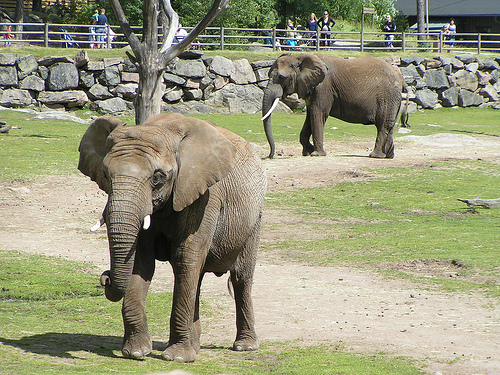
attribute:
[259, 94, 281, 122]
tusk — white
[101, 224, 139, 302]
trunk — gray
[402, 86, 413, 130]
tail — black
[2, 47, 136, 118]
rocks — gray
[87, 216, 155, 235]
tusks — white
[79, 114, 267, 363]
elephant — standing, short, long, gray, walking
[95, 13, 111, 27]
shirt — blue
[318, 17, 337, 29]
shirt — black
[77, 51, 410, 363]
elephants — fenced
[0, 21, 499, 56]
fence — metal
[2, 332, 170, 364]
shadow — cast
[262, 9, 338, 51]
people — row, watching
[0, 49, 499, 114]
wall — stone, rock